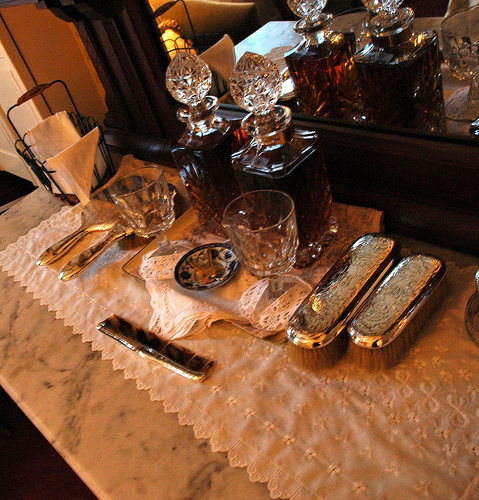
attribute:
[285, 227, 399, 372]
brush — big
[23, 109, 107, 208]
napkin — white 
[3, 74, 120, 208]
black basket — black 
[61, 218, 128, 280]
handle — silver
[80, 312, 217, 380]
comb — is gold, is black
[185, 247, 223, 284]
keys — gold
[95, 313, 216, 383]
comb — is gold, is metal, silver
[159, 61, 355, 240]
bottle toppers — glass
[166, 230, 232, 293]
saucer — blue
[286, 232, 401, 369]
silver brush — is silver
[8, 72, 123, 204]
basket — metal-framed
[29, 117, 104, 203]
cloth — white, folded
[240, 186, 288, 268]
glass — clear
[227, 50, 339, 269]
bottle — large, whiskey, scotch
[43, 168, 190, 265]
mirror — hand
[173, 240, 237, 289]
dish — small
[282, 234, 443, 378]
brushes — rectangluar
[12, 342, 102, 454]
top — marble